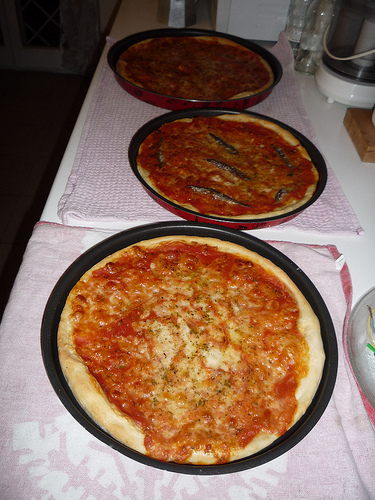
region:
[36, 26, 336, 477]
three pizzas in pants ready for baking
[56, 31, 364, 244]
white cloth under two pizzas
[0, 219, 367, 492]
white cloth under a single pizza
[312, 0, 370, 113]
white and gray food processor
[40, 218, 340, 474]
cheese and sauce pizza in a pan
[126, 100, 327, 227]
anchovy pizza in a pan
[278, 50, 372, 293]
white countertop under pizza and appliances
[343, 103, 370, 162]
piece of wood on a white counter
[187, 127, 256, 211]
anchovies on a pizza in a pan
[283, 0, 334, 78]
salt and pepper shakers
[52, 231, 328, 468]
A whole cheese pizza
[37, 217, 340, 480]
A whole cheese pizza on a black plate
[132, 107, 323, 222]
A deep dish sausage pizza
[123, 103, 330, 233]
A sausage pizza on a black and red pan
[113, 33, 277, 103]
A deep dish cheese pizza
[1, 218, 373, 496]
A pink dish towel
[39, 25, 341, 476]
Three pizza's on a table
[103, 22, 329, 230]
Two pizzas on a table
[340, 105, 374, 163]
A wooden block on a table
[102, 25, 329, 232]
Two pizzas on black and red pans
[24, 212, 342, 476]
cooked pizza in a pan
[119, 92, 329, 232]
cooked pizza in a pan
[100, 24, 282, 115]
cooked pizza in a pan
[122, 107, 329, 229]
pizza in a black pan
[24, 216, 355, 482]
pizza in a black pan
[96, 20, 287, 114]
pizza in a black pan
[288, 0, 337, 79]
clear glass bottle on the table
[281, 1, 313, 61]
clear glass bottle on the table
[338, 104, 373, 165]
wooden block on the table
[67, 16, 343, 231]
two pizzas in two pans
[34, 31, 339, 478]
three pizzas on a table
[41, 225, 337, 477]
a cheese pizza in a black dish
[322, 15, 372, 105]
a food processor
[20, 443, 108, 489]
a pink and white tablecloth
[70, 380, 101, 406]
the crust of the pizza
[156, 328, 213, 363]
cheese on the pizza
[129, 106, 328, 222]
a pizza in a red dish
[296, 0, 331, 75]
a tall glass on the counter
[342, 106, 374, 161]
part of a wooden block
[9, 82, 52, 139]
the floor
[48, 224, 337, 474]
Pizza on the black dish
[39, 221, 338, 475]
A black dish on the table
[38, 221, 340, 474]
The black dish is circular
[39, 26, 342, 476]
Three pizzas on the table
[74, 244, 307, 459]
Melted cheese on the pizza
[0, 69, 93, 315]
The ground below the table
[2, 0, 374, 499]
A table beneath the pizzas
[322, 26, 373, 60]
A cord on the appliance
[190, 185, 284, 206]
An ingredient on the pizza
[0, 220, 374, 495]
A cloth beneath the pizza dish